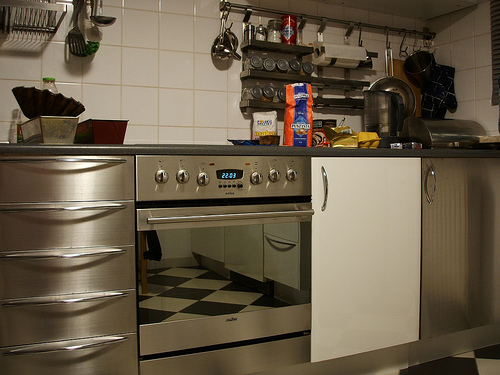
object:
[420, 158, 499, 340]
cabinet door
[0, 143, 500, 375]
cabinet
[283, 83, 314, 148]
bag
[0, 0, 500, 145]
wall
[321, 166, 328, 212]
handle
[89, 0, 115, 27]
utensils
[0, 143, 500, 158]
counter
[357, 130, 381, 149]
product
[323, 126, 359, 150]
product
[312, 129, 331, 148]
product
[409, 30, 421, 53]
hook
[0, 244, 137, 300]
drawers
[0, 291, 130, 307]
handles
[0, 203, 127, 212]
handles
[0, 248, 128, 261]
handles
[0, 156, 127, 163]
handles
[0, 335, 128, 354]
handles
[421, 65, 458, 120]
mitt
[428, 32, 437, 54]
hook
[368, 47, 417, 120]
frying pan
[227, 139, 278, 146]
packet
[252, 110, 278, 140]
flour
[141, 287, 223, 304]
reflection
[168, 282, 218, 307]
oven door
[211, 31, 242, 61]
silver funnel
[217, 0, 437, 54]
rack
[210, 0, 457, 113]
kitchen appliances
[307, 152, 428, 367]
elephant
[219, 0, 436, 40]
rail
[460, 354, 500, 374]
floor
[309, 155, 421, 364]
cabinet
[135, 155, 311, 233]
oven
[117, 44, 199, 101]
tiles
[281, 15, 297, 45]
canister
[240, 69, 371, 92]
shelf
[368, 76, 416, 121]
pan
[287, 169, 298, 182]
knob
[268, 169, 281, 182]
knob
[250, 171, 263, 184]
knob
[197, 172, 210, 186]
knob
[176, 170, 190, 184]
knob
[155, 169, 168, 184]
knob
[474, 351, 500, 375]
tiles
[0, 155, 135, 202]
drawer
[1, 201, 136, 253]
drawer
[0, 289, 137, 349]
drawer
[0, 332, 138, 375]
drawer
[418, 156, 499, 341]
cabinet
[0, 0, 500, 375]
kitchen